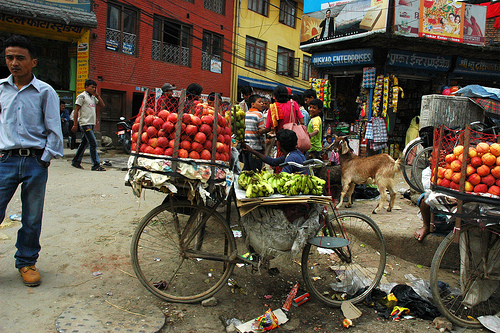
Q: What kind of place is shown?
A: It is a market.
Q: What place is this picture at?
A: It is at the market.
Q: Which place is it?
A: It is a market.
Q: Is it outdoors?
A: Yes, it is outdoors.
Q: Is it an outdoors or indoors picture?
A: It is outdoors.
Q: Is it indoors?
A: No, it is outdoors.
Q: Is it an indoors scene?
A: No, it is outdoors.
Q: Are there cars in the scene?
A: No, there are no cars.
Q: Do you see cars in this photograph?
A: No, there are no cars.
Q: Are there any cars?
A: No, there are no cars.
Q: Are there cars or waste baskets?
A: No, there are no cars or waste baskets.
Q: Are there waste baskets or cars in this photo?
A: No, there are no cars or waste baskets.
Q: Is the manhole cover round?
A: Yes, the manhole cover is round.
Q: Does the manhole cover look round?
A: Yes, the manhole cover is round.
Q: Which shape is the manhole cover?
A: The manhole cover is round.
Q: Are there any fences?
A: No, there are no fences.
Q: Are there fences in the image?
A: No, there are no fences.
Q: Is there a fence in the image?
A: No, there are no fences.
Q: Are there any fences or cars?
A: No, there are no fences or cars.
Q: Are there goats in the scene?
A: Yes, there is a goat.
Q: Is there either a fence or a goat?
A: Yes, there is a goat.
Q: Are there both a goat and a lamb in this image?
A: No, there is a goat but no lambs.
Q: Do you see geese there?
A: No, there are no geese.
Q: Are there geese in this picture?
A: No, there are no geese.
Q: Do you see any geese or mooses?
A: No, there are no geese or mooses.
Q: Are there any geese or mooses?
A: No, there are no geese or mooses.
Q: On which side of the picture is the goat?
A: The goat is on the right of the image.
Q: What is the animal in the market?
A: The animal is a goat.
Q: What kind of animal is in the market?
A: The animal is a goat.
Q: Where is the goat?
A: The goat is in the market.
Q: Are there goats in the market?
A: Yes, there is a goat in the market.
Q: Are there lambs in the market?
A: No, there is a goat in the market.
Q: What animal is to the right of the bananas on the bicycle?
A: The animal is a goat.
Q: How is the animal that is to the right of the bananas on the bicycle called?
A: The animal is a goat.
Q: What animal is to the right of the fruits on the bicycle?
A: The animal is a goat.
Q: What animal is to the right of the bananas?
A: The animal is a goat.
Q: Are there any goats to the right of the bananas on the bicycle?
A: Yes, there is a goat to the right of the bananas.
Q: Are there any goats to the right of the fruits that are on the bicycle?
A: Yes, there is a goat to the right of the bananas.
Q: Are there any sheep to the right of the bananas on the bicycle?
A: No, there is a goat to the right of the bananas.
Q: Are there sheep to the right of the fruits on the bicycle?
A: No, there is a goat to the right of the bananas.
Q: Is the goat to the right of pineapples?
A: No, the goat is to the right of the bananas.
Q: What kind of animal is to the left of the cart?
A: The animal is a goat.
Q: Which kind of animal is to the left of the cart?
A: The animal is a goat.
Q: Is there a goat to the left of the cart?
A: Yes, there is a goat to the left of the cart.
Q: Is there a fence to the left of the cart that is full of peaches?
A: No, there is a goat to the left of the cart.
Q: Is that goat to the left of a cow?
A: No, the goat is to the left of a cart.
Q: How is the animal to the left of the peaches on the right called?
A: The animal is a goat.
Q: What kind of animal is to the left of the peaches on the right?
A: The animal is a goat.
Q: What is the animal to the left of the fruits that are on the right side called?
A: The animal is a goat.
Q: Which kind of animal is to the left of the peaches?
A: The animal is a goat.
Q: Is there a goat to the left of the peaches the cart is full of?
A: Yes, there is a goat to the left of the peaches.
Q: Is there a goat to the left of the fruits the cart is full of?
A: Yes, there is a goat to the left of the peaches.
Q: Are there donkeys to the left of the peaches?
A: No, there is a goat to the left of the peaches.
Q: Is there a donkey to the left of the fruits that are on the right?
A: No, there is a goat to the left of the peaches.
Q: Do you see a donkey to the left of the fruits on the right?
A: No, there is a goat to the left of the peaches.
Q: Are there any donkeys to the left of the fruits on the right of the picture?
A: No, there is a goat to the left of the peaches.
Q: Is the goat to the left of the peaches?
A: Yes, the goat is to the left of the peaches.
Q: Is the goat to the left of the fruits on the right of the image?
A: Yes, the goat is to the left of the peaches.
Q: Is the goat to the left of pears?
A: No, the goat is to the left of the peaches.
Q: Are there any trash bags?
A: Yes, there is a trash bag.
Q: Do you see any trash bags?
A: Yes, there is a trash bag.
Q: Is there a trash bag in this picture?
A: Yes, there is a trash bag.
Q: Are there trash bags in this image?
A: Yes, there is a trash bag.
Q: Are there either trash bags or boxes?
A: Yes, there is a trash bag.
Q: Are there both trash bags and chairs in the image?
A: No, there is a trash bag but no chairs.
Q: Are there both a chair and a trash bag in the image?
A: No, there is a trash bag but no chairs.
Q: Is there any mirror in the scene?
A: No, there are no mirrors.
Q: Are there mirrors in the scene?
A: No, there are no mirrors.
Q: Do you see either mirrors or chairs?
A: No, there are no mirrors or chairs.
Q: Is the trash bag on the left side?
A: No, the trash bag is on the right of the image.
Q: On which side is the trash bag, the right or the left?
A: The trash bag is on the right of the image.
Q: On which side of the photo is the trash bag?
A: The trash bag is on the right of the image.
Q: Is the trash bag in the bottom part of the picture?
A: Yes, the trash bag is in the bottom of the image.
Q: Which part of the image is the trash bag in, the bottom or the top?
A: The trash bag is in the bottom of the image.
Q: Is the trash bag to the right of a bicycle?
A: Yes, the trash bag is to the right of a bicycle.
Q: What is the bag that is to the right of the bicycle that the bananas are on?
A: The bag is a trash bag.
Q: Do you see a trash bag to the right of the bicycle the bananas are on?
A: Yes, there is a trash bag to the right of the bicycle.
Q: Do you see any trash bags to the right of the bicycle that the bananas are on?
A: Yes, there is a trash bag to the right of the bicycle.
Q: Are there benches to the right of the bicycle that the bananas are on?
A: No, there is a trash bag to the right of the bicycle.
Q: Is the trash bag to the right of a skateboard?
A: No, the trash bag is to the right of the bicycle.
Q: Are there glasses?
A: No, there are no glasses.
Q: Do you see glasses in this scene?
A: No, there are no glasses.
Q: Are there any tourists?
A: No, there are no tourists.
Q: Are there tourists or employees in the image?
A: No, there are no tourists or employees.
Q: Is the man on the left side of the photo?
A: Yes, the man is on the left of the image.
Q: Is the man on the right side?
A: No, the man is on the left of the image.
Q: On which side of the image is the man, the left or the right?
A: The man is on the left of the image.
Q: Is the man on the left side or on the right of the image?
A: The man is on the left of the image.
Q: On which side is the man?
A: The man is on the left of the image.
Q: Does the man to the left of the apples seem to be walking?
A: Yes, the man is walking.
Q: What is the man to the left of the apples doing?
A: The man is walking.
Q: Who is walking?
A: The man is walking.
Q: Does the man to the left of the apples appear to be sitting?
A: No, the man is walking.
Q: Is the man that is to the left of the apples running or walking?
A: The man is walking.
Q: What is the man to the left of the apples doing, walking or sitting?
A: The man is walking.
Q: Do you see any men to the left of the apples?
A: Yes, there is a man to the left of the apples.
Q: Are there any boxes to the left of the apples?
A: No, there is a man to the left of the apples.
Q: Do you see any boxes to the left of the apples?
A: No, there is a man to the left of the apples.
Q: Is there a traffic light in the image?
A: No, there are no traffic lights.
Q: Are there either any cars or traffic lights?
A: No, there are no traffic lights or cars.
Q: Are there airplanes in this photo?
A: No, there are no airplanes.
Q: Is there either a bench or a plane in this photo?
A: No, there are no airplanes or benches.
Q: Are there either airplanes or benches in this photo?
A: No, there are no airplanes or benches.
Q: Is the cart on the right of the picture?
A: Yes, the cart is on the right of the image.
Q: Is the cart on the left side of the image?
A: No, the cart is on the right of the image.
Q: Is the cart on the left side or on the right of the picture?
A: The cart is on the right of the image.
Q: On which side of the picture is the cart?
A: The cart is on the right of the image.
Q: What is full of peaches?
A: The cart is full of peaches.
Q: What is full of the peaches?
A: The cart is full of peaches.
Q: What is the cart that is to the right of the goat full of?
A: The cart is full of peaches.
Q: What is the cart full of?
A: The cart is full of peaches.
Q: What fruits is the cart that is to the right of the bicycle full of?
A: The cart is full of peaches.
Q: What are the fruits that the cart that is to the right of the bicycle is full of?
A: The fruits are peaches.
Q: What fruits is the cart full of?
A: The cart is full of peaches.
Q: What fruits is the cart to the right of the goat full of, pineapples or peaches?
A: The cart is full of peaches.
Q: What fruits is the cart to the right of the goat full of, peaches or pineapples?
A: The cart is full of peaches.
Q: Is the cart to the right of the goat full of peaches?
A: Yes, the cart is full of peaches.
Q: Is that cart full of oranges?
A: No, the cart is full of peaches.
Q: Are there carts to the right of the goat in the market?
A: Yes, there is a cart to the right of the goat.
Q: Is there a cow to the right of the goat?
A: No, there is a cart to the right of the goat.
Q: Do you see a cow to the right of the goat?
A: No, there is a cart to the right of the goat.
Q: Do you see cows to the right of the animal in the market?
A: No, there is a cart to the right of the goat.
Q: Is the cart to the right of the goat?
A: Yes, the cart is to the right of the goat.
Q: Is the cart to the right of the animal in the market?
A: Yes, the cart is to the right of the goat.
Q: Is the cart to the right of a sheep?
A: No, the cart is to the right of the goat.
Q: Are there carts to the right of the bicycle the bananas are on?
A: Yes, there is a cart to the right of the bicycle.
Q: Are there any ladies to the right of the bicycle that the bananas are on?
A: No, there is a cart to the right of the bicycle.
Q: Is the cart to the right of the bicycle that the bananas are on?
A: Yes, the cart is to the right of the bicycle.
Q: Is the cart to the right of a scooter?
A: No, the cart is to the right of the bicycle.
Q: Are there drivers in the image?
A: No, there are no drivers.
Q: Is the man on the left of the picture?
A: Yes, the man is on the left of the image.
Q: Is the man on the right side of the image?
A: No, the man is on the left of the image.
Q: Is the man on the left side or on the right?
A: The man is on the left of the image.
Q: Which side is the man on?
A: The man is on the left of the image.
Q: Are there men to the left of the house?
A: Yes, there is a man to the left of the house.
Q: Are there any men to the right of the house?
A: No, the man is to the left of the house.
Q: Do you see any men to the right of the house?
A: No, the man is to the left of the house.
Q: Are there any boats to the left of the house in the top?
A: No, there is a man to the left of the house.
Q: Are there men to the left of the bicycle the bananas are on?
A: Yes, there is a man to the left of the bicycle.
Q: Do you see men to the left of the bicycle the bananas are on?
A: Yes, there is a man to the left of the bicycle.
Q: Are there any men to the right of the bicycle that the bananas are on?
A: No, the man is to the left of the bicycle.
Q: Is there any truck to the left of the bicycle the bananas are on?
A: No, there is a man to the left of the bicycle.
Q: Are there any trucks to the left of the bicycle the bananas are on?
A: No, there is a man to the left of the bicycle.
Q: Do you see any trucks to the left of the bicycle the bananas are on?
A: No, there is a man to the left of the bicycle.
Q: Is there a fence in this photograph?
A: No, there are no fences.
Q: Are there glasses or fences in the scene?
A: No, there are no fences or glasses.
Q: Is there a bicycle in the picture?
A: Yes, there is a bicycle.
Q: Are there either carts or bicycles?
A: Yes, there is a bicycle.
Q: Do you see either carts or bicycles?
A: Yes, there is a bicycle.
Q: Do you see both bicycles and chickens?
A: No, there is a bicycle but no chickens.